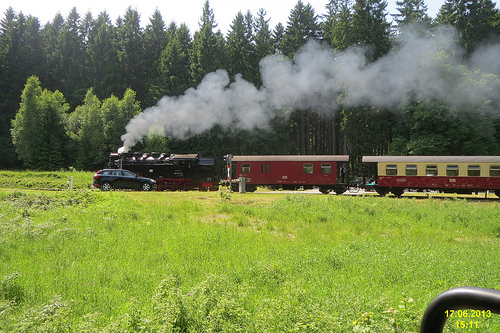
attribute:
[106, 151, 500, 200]
train — black, white, long, moving, movin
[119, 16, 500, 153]
smoke — white, steam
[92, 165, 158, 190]
car — black, blue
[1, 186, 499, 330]
grass — long, green, weeds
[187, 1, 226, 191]
tree — tall, pine, leaves, green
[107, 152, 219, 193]
engine — black, red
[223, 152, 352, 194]
passenger car — red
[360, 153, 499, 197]
passenger car — yellow, red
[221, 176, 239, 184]
arm — down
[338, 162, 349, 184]
conductor — standing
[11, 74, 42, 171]
bush — lush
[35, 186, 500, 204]
road — dirt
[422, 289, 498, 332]
pole — rusty, brown, metal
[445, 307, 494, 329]
time stamp — yellow, date